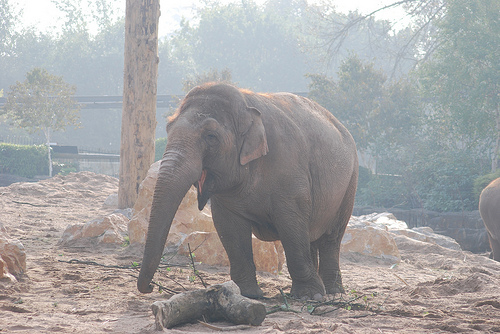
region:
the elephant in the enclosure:
[136, 83, 356, 299]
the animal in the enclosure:
[136, 83, 357, 302]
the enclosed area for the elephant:
[0, 84, 499, 332]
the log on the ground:
[150, 278, 266, 332]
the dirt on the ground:
[1, 169, 498, 330]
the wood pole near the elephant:
[117, 0, 159, 207]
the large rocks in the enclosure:
[0, 160, 497, 302]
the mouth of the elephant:
[191, 168, 213, 210]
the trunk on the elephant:
[136, 140, 203, 293]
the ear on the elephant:
[238, 107, 268, 165]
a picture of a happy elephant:
[21, 17, 440, 317]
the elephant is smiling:
[90, 65, 353, 314]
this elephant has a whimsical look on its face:
[116, 74, 280, 222]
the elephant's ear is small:
[222, 90, 276, 169]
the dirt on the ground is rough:
[7, 180, 134, 306]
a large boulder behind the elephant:
[123, 160, 285, 276]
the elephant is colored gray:
[115, 74, 360, 316]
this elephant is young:
[100, 71, 365, 312]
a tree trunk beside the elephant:
[118, 6, 163, 216]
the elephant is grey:
[143, 79, 378, 304]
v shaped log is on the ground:
[148, 276, 265, 332]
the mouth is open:
[190, 167, 220, 205]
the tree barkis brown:
[111, 18, 162, 165]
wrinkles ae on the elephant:
[269, 186, 319, 233]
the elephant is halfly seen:
[471, 173, 498, 258]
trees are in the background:
[213, 16, 473, 88]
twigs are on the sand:
[291, 286, 360, 313]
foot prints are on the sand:
[53, 267, 113, 311]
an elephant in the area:
[27, 7, 432, 321]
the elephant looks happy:
[98, 65, 408, 310]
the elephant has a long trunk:
[106, 122, 202, 303]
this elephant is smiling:
[177, 157, 232, 222]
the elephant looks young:
[99, 73, 270, 239]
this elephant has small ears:
[228, 100, 278, 170]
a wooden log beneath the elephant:
[123, 257, 266, 329]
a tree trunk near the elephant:
[112, 1, 162, 204]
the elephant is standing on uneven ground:
[5, 192, 170, 322]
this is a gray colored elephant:
[110, 68, 365, 290]